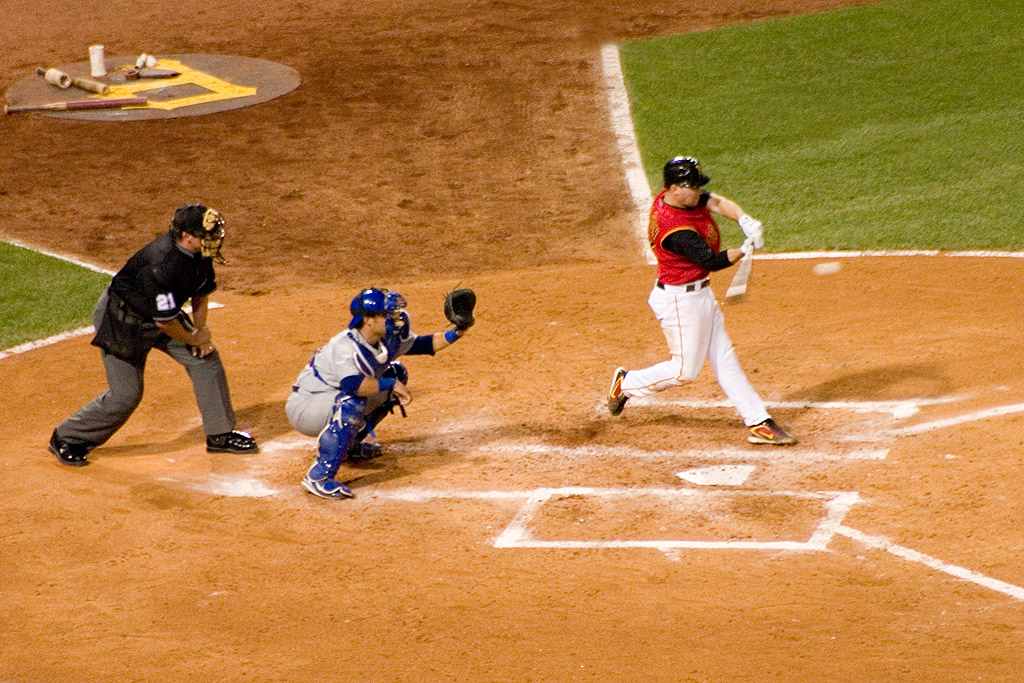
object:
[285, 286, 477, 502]
catcher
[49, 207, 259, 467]
referee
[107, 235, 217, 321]
shirt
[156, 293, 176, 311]
numbers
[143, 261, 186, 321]
sleeve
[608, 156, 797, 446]
batter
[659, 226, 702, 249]
trim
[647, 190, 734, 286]
shirt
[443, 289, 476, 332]
catcher's mitt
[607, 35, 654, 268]
lines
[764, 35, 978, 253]
grass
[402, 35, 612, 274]
dirt